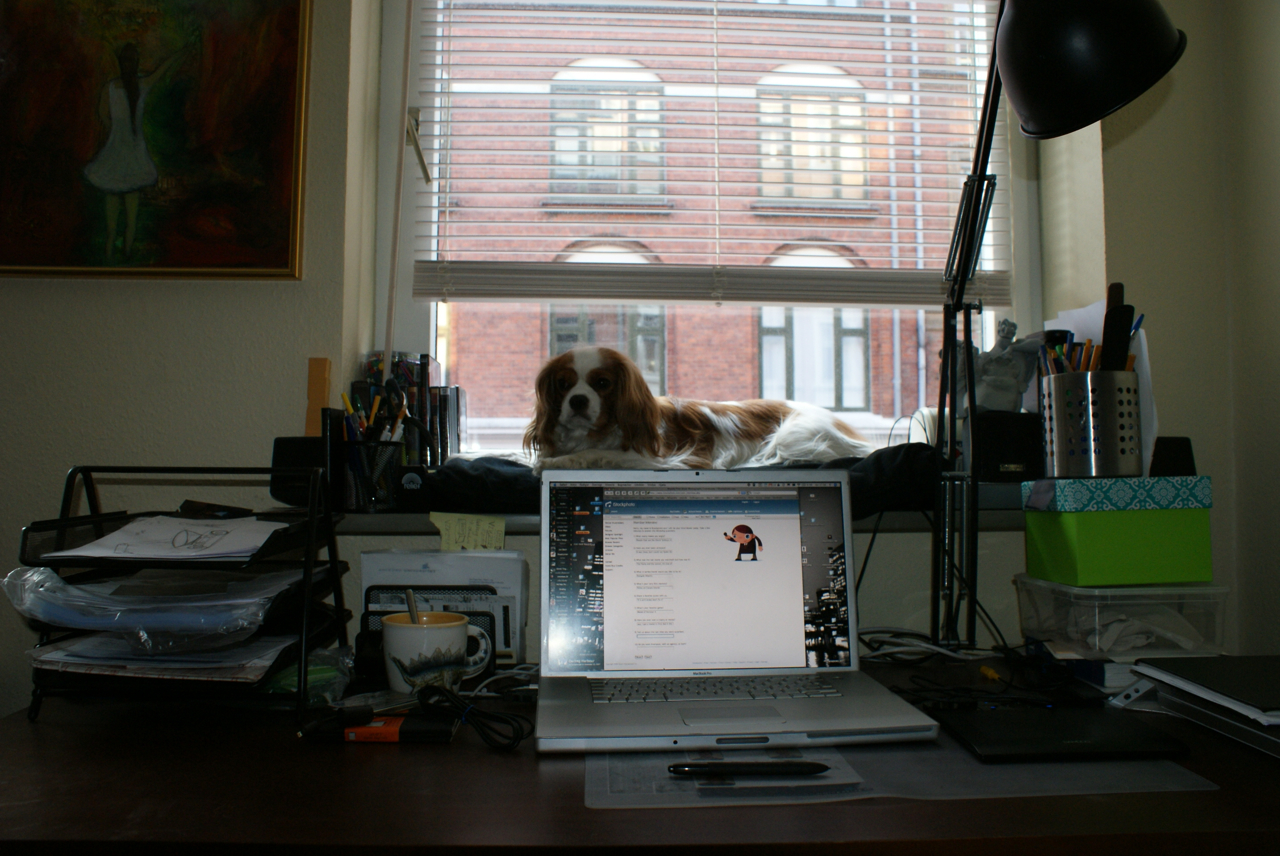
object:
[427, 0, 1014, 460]
window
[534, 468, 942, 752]
laptop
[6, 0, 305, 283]
painting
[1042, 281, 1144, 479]
container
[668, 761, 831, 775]
pen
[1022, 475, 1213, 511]
top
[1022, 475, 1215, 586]
box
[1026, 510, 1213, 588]
bottom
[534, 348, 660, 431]
head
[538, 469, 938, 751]
computer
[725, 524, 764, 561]
cartoon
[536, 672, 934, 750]
keyboard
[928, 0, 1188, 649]
lamp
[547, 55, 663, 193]
window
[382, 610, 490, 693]
cup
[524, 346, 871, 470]
dog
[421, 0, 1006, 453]
building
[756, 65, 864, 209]
window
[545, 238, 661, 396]
window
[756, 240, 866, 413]
window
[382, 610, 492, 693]
mug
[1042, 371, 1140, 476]
container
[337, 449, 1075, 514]
windowsill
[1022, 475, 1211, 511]
lid